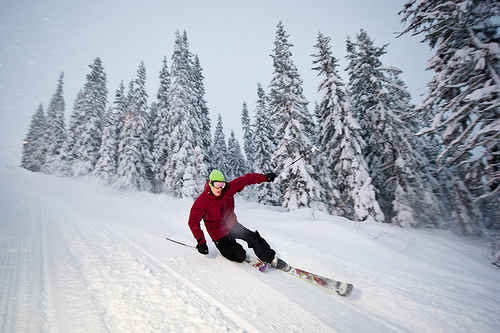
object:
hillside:
[0, 163, 500, 329]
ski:
[262, 258, 367, 296]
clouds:
[61, 24, 133, 55]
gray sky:
[5, 3, 93, 42]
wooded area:
[22, 0, 498, 237]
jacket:
[187, 172, 267, 244]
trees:
[312, 25, 382, 217]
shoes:
[257, 257, 288, 269]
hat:
[209, 170, 227, 188]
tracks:
[4, 167, 247, 333]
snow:
[0, 163, 499, 333]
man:
[186, 169, 285, 270]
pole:
[268, 149, 316, 180]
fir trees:
[252, 19, 327, 211]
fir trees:
[153, 26, 210, 202]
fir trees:
[64, 44, 109, 184]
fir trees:
[342, 25, 448, 230]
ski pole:
[163, 233, 202, 255]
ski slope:
[2, 174, 425, 317]